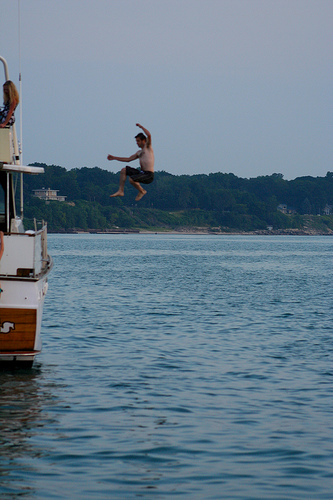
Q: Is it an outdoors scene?
A: Yes, it is outdoors.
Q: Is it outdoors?
A: Yes, it is outdoors.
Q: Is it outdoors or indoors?
A: It is outdoors.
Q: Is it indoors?
A: No, it is outdoors.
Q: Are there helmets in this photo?
A: No, there are no helmets.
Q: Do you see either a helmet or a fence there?
A: No, there are no helmets or fences.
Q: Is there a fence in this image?
A: No, there are no fences.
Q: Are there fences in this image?
A: No, there are no fences.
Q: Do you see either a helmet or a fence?
A: No, there are no fences or helmets.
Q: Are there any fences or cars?
A: No, there are no fences or cars.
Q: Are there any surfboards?
A: No, there are no surfboards.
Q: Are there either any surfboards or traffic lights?
A: No, there are no surfboards or traffic lights.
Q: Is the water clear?
A: Yes, the water is clear.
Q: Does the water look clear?
A: Yes, the water is clear.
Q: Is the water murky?
A: No, the water is clear.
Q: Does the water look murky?
A: No, the water is clear.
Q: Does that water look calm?
A: Yes, the water is calm.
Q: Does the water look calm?
A: Yes, the water is calm.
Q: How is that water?
A: The water is calm.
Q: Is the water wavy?
A: No, the water is calm.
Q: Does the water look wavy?
A: No, the water is calm.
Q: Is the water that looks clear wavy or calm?
A: The water is calm.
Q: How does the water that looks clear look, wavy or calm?
A: The water is calm.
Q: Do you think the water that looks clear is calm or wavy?
A: The water is calm.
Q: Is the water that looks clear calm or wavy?
A: The water is calm.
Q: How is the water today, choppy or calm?
A: The water is calm.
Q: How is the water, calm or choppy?
A: The water is calm.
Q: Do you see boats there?
A: Yes, there is a boat.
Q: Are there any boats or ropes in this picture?
A: Yes, there is a boat.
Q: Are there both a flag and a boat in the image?
A: No, there is a boat but no flags.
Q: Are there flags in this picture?
A: No, there are no flags.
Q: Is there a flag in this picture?
A: No, there are no flags.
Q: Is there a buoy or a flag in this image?
A: No, there are no flags or buoys.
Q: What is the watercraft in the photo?
A: The watercraft is a boat.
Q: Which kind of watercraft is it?
A: The watercraft is a boat.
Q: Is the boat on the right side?
A: No, the boat is on the left of the image.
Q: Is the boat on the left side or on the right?
A: The boat is on the left of the image.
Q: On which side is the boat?
A: The boat is on the left of the image.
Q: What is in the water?
A: The boat is in the water.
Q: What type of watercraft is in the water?
A: The watercraft is a boat.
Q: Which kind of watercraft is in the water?
A: The watercraft is a boat.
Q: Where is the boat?
A: The boat is in the water.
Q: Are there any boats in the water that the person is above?
A: Yes, there is a boat in the water.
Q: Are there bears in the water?
A: No, there is a boat in the water.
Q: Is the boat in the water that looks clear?
A: Yes, the boat is in the water.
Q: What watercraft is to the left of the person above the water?
A: The watercraft is a boat.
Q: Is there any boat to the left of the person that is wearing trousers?
A: Yes, there is a boat to the left of the person.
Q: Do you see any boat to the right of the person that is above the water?
A: No, the boat is to the left of the person.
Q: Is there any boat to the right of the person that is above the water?
A: No, the boat is to the left of the person.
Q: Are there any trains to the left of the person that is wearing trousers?
A: No, there is a boat to the left of the person.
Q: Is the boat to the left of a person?
A: Yes, the boat is to the left of a person.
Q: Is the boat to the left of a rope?
A: No, the boat is to the left of a person.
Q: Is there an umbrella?
A: No, there are no umbrellas.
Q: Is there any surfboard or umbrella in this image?
A: No, there are no umbrellas or surfboards.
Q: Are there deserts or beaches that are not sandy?
A: No, there is a beach but it is sandy.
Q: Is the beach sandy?
A: Yes, the beach is sandy.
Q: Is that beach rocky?
A: No, the beach is sandy.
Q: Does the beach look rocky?
A: No, the beach is sandy.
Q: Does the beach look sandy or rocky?
A: The beach is sandy.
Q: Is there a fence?
A: No, there are no fences.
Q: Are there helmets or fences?
A: No, there are no fences or helmets.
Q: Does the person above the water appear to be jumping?
A: Yes, the person is jumping.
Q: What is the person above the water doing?
A: The person is jumping.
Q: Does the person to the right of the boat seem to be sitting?
A: No, the person is jumping.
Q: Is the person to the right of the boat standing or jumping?
A: The person is jumping.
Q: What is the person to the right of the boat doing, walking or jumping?
A: The person is jumping.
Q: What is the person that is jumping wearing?
A: The person is wearing trousers.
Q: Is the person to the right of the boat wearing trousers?
A: Yes, the person is wearing trousers.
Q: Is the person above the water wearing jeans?
A: No, the person is wearing trousers.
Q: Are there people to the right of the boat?
A: Yes, there is a person to the right of the boat.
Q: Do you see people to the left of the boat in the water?
A: No, the person is to the right of the boat.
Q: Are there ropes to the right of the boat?
A: No, there is a person to the right of the boat.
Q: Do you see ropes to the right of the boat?
A: No, there is a person to the right of the boat.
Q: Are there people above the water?
A: Yes, there is a person above the water.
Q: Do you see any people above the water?
A: Yes, there is a person above the water.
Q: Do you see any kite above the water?
A: No, there is a person above the water.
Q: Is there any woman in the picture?
A: Yes, there is a woman.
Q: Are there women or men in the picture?
A: Yes, there is a woman.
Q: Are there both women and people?
A: Yes, there are both a woman and a person.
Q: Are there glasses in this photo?
A: No, there are no glasses.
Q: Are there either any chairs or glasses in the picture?
A: No, there are no glasses or chairs.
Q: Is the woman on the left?
A: Yes, the woman is on the left of the image.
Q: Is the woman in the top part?
A: Yes, the woman is in the top of the image.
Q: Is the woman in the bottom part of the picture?
A: No, the woman is in the top of the image.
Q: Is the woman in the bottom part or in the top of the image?
A: The woman is in the top of the image.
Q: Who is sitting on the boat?
A: The woman is sitting on the boat.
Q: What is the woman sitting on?
A: The woman is sitting on the boat.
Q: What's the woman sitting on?
A: The woman is sitting on the boat.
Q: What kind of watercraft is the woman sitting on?
A: The woman is sitting on the boat.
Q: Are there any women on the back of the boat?
A: Yes, there is a woman on the back of the boat.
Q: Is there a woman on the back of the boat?
A: Yes, there is a woman on the back of the boat.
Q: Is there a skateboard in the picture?
A: No, there are no skateboards.